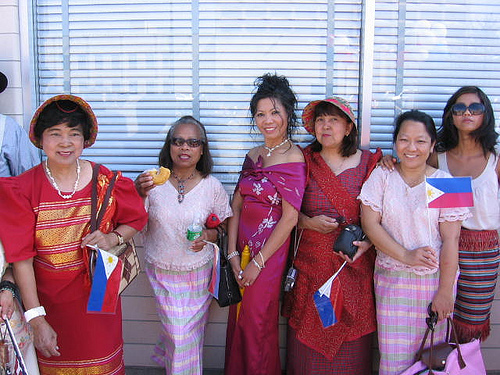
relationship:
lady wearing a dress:
[0, 93, 147, 375] [220, 154, 308, 372]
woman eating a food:
[132, 113, 234, 373] [142, 165, 171, 187]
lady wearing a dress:
[0, 93, 147, 375] [0, 158, 150, 372]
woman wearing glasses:
[431, 83, 484, 336] [449, 101, 484, 118]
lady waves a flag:
[0, 93, 147, 375] [421, 172, 476, 249]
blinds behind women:
[32, 1, 483, 188] [2, 70, 481, 370]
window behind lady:
[19, 3, 484, 196] [0, 93, 147, 375]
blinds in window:
[32, 1, 483, 188] [19, 3, 484, 196]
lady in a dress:
[0, 93, 147, 375] [0, 158, 150, 372]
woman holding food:
[132, 113, 234, 375] [142, 165, 172, 186]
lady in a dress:
[0, 93, 147, 375] [220, 154, 308, 372]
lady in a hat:
[0, 93, 147, 375] [298, 92, 359, 137]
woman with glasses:
[372, 84, 500, 343] [449, 101, 484, 118]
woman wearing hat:
[294, 90, 384, 371] [300, 91, 361, 141]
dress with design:
[228, 141, 305, 371] [249, 175, 284, 251]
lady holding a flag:
[0, 93, 147, 375] [81, 239, 126, 317]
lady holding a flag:
[0, 93, 147, 375] [313, 274, 351, 324]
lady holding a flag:
[0, 93, 147, 375] [428, 174, 474, 214]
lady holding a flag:
[0, 93, 147, 375] [87, 241, 127, 318]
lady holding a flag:
[0, 93, 147, 375] [426, 172, 474, 218]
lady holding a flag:
[0, 93, 147, 375] [91, 243, 125, 320]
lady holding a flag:
[0, 93, 147, 375] [199, 239, 226, 296]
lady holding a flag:
[226, 76, 291, 358] [308, 269, 349, 329]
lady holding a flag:
[0, 93, 147, 375] [318, 273, 350, 332]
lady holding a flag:
[0, 93, 147, 375] [422, 173, 477, 213]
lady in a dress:
[0, 93, 147, 375] [39, 210, 96, 356]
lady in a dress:
[0, 93, 147, 375] [236, 156, 303, 255]